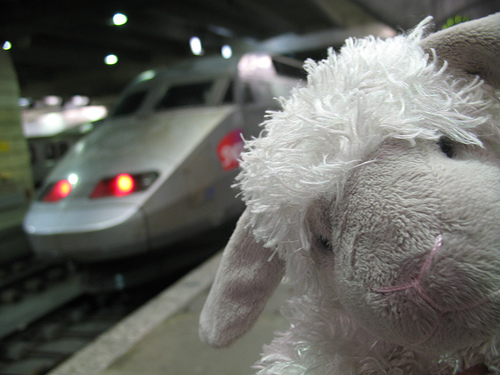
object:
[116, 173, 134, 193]
headlight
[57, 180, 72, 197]
headlight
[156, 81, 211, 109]
windscreen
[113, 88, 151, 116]
windscreen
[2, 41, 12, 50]
light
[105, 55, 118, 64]
light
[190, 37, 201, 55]
light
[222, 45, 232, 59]
light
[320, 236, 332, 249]
eye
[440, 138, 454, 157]
eye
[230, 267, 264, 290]
section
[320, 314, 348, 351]
section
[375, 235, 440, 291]
nose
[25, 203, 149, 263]
front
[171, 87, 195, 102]
part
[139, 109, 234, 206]
edge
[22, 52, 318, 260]
train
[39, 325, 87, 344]
part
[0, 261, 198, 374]
rail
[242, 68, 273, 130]
side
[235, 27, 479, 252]
hair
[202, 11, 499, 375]
toy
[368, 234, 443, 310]
configuration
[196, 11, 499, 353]
head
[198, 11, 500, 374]
angle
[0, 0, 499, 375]
background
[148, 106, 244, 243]
side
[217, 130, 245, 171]
logo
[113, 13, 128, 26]
lights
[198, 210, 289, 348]
ear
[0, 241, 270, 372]
ground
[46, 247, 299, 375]
platform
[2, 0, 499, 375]
train station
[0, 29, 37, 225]
column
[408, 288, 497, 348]
mouth